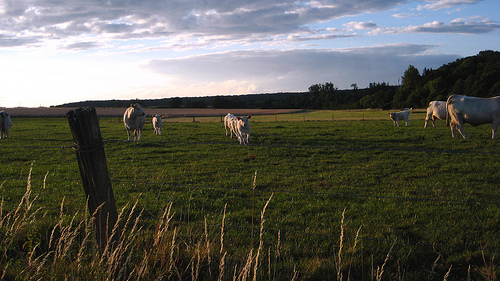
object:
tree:
[315, 80, 338, 110]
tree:
[379, 88, 395, 103]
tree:
[420, 66, 434, 86]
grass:
[0, 109, 500, 281]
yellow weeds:
[0, 158, 500, 281]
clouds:
[137, 41, 468, 95]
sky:
[0, 0, 500, 108]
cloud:
[390, 0, 485, 18]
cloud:
[343, 16, 499, 35]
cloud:
[0, 0, 412, 52]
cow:
[123, 101, 147, 141]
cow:
[151, 113, 164, 136]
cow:
[233, 114, 253, 145]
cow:
[443, 93, 500, 140]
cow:
[422, 99, 448, 129]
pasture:
[1, 116, 500, 281]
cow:
[388, 107, 413, 128]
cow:
[0, 109, 18, 141]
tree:
[398, 63, 424, 109]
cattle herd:
[0, 93, 499, 146]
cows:
[222, 111, 238, 138]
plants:
[0, 159, 500, 281]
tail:
[444, 95, 452, 130]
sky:
[358, 44, 480, 47]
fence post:
[65, 104, 130, 280]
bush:
[380, 102, 394, 111]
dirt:
[0, 107, 307, 116]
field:
[0, 107, 500, 281]